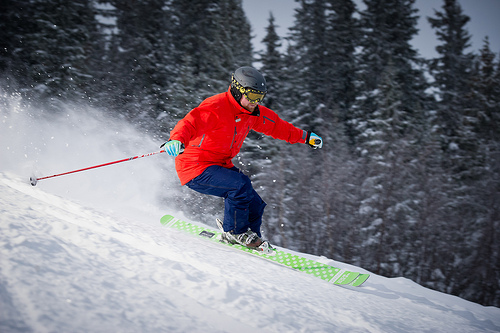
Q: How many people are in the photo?
A: One.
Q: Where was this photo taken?
A: On a ski mountain.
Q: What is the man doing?
A: Skiing.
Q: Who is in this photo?
A: A skier.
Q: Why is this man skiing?
A: For fun.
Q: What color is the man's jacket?
A: Red.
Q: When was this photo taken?
A: In the daytime.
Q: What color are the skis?
A: Green.